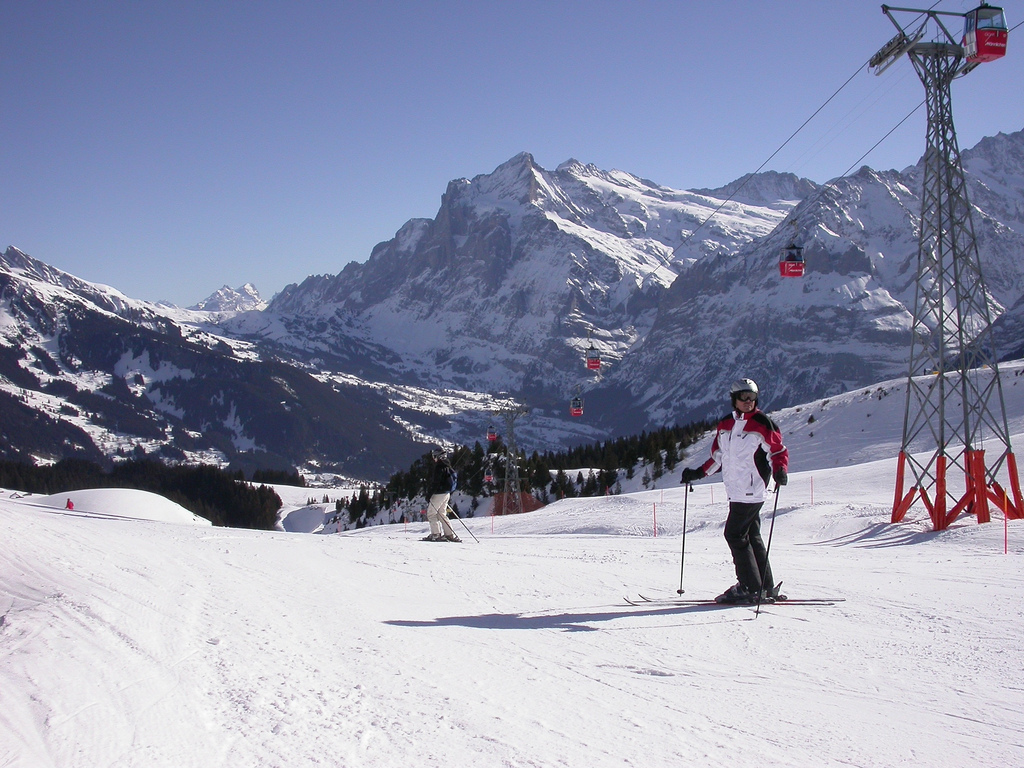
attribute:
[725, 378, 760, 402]
helmet — white, black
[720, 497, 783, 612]
pants — black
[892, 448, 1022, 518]
paint — red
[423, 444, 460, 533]
guy — skiing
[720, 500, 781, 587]
pants — long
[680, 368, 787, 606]
skier — Stationary, helmeted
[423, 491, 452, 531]
trousers — light colored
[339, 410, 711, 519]
trees — evergreens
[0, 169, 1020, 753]
ski area — snow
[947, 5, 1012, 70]
gondola — red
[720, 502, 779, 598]
pants — black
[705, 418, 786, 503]
parka — white, black, red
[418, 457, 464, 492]
parka — black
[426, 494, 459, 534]
pants — white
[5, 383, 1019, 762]
snow — packed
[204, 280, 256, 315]
mountain peak — in the background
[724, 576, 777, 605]
boots — black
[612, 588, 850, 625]
skis — white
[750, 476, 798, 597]
pole — gray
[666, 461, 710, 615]
pole — gray